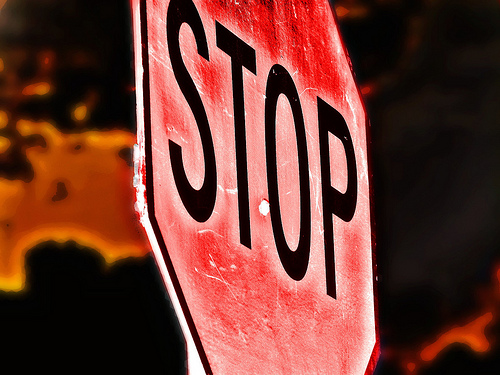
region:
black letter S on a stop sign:
[161, 1, 216, 232]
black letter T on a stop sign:
[213, 18, 255, 248]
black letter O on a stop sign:
[262, 63, 312, 280]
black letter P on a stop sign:
[316, 94, 361, 305]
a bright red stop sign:
[131, 1, 377, 374]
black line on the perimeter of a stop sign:
[138, 0, 158, 223]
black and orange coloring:
[1, 1, 134, 373]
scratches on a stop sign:
[190, 222, 234, 292]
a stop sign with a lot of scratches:
[135, 1, 380, 374]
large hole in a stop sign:
[258, 198, 272, 218]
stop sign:
[65, 0, 451, 358]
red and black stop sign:
[105, 2, 425, 374]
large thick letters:
[153, 4, 384, 277]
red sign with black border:
[96, 41, 419, 335]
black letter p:
[305, 84, 382, 301]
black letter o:
[257, 48, 319, 281]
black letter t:
[207, 5, 263, 260]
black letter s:
[129, 0, 216, 232]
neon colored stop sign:
[10, 2, 467, 365]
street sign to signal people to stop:
[50, 2, 421, 367]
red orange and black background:
[4, 12, 228, 335]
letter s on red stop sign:
[168, 0, 220, 238]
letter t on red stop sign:
[209, 44, 255, 263]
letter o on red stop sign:
[247, 67, 311, 284]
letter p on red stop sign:
[306, 87, 355, 307]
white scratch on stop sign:
[230, 327, 251, 356]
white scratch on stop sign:
[202, 263, 231, 303]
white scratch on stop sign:
[198, 227, 217, 250]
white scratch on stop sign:
[157, 144, 160, 171]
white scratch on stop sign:
[293, 62, 316, 83]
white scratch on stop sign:
[295, 42, 315, 54]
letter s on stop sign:
[158, 0, 220, 235]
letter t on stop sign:
[209, 22, 264, 257]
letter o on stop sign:
[261, 58, 314, 280]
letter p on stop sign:
[311, 91, 361, 307]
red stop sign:
[128, 1, 418, 373]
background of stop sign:
[18, 87, 147, 294]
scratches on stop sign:
[210, 287, 252, 349]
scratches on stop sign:
[251, 190, 268, 228]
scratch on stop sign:
[354, 159, 378, 200]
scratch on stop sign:
[280, 24, 334, 69]